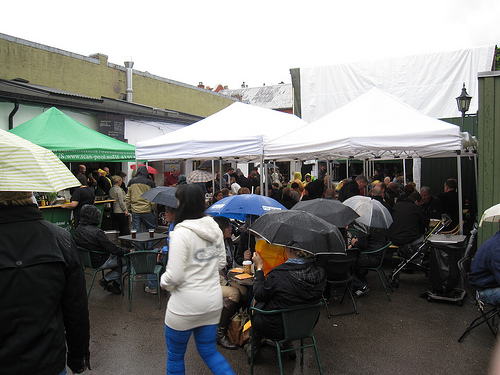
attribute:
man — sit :
[74, 186, 131, 292]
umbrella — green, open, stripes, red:
[37, 105, 128, 168]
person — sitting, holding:
[205, 233, 364, 342]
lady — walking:
[96, 171, 235, 331]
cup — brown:
[134, 214, 167, 246]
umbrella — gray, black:
[274, 202, 324, 250]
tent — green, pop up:
[53, 103, 120, 170]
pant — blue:
[148, 325, 256, 375]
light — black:
[436, 77, 479, 121]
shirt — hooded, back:
[184, 207, 238, 256]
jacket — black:
[266, 265, 339, 301]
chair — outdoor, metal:
[234, 282, 364, 349]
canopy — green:
[39, 120, 111, 164]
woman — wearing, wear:
[133, 231, 256, 300]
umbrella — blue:
[235, 185, 264, 215]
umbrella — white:
[208, 101, 278, 141]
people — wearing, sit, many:
[322, 153, 442, 240]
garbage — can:
[408, 219, 476, 302]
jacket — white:
[171, 262, 218, 321]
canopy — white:
[338, 101, 399, 160]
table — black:
[125, 236, 164, 298]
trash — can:
[425, 248, 463, 299]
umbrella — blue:
[241, 190, 270, 218]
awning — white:
[214, 75, 383, 160]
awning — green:
[32, 85, 86, 136]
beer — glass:
[114, 224, 157, 251]